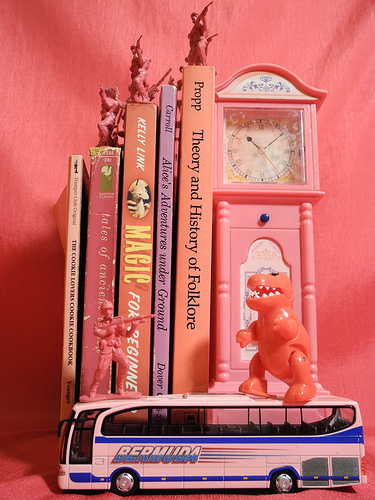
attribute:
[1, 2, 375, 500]
background — pink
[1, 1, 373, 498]
pink — bright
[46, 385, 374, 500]
tour bus — toy, white, blue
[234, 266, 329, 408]
tyrannosaurus rex — toy, pink, orange, standing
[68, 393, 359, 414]
roof — white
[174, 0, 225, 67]
toy soldier — pink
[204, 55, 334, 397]
grandfather clock — pink, toy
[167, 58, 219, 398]
book — lined up, stacked, vertical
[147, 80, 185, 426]
book — lined up, stacked, vertical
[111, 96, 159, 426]
book — lined up, stacked, vertical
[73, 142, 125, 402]
book — lined up, stacked, vertical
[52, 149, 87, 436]
book — lined up, stacked, vertical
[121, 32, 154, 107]
toy soldier — pink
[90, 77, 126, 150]
toy soldier — pink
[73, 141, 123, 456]
cover — worn, scuffed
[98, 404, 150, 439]
window — transparent, long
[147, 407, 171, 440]
window — transparent, long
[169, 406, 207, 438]
window — transparent, long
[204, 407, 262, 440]
window — transparent, long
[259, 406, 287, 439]
window — transparent, long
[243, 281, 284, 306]
teeth — white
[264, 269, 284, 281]
eye — black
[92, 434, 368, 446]
line — blue